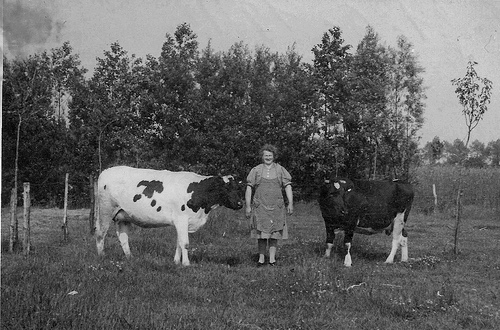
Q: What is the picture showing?
A: It is showing a field.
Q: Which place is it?
A: It is a field.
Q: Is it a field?
A: Yes, it is a field.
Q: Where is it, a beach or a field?
A: It is a field.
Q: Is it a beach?
A: No, it is a field.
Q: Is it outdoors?
A: Yes, it is outdoors.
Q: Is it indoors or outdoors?
A: It is outdoors.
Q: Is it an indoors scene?
A: No, it is outdoors.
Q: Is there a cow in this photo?
A: Yes, there is a cow.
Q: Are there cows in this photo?
A: Yes, there is a cow.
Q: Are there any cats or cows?
A: Yes, there is a cow.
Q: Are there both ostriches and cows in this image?
A: No, there is a cow but no ostriches.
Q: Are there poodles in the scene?
A: No, there are no poodles.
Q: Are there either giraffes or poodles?
A: No, there are no poodles or giraffes.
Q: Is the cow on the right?
A: Yes, the cow is on the right of the image.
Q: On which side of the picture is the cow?
A: The cow is on the right of the image.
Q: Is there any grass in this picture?
A: Yes, there is grass.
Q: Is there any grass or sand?
A: Yes, there is grass.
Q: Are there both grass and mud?
A: No, there is grass but no mud.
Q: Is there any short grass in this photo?
A: Yes, there is short grass.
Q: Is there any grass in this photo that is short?
A: Yes, there is grass that is short.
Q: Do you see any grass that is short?
A: Yes, there is grass that is short.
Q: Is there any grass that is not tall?
A: Yes, there is short grass.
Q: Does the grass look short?
A: Yes, the grass is short.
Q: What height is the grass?
A: The grass is short.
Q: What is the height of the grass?
A: The grass is short.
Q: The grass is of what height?
A: The grass is short.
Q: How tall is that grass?
A: The grass is short.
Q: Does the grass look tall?
A: No, the grass is short.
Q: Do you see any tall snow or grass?
A: No, there is grass but it is short.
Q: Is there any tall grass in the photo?
A: No, there is grass but it is short.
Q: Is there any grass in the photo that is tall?
A: No, there is grass but it is short.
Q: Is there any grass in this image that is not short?
A: No, there is grass but it is short.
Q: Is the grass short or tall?
A: The grass is short.